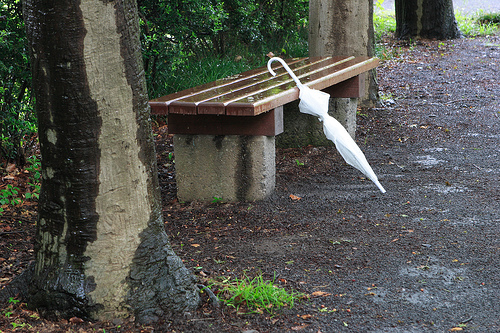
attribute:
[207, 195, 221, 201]
growth — green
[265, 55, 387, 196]
umbrella — white, closed, curved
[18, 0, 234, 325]
bark — brown, tan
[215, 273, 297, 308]
grass — patch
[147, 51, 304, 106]
board — wooden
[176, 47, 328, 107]
board — wooden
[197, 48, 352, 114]
board — wooden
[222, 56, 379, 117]
board — wooden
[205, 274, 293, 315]
grass — bright, green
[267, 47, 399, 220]
umbrella — white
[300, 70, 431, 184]
umbrella — white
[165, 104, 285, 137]
piece — wooden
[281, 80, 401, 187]
umbrella — white, closed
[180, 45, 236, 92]
grass — wild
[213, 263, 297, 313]
grass — green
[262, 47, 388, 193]
umbrella — slanted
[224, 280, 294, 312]
grass — green, small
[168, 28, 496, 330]
ground — dark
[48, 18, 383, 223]
trees — large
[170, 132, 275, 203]
legs — stone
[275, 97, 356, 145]
legs — stone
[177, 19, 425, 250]
bench — wood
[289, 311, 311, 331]
leaves — dried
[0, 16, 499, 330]
ground — muddy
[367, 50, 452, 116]
leaves — brown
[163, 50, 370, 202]
bench — wood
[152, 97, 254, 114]
planks — wooden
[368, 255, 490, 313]
spot — wet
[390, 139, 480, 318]
puddles — small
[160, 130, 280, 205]
base — concrete